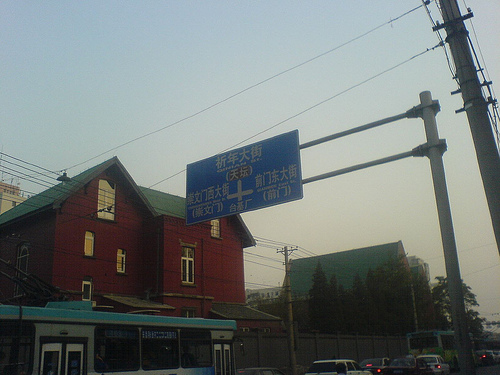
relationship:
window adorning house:
[97, 178, 117, 221] [2, 152, 284, 332]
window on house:
[97, 178, 117, 221] [5, 152, 286, 373]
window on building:
[97, 178, 117, 221] [0, 159, 254, 369]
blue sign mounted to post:
[187, 129, 303, 226] [417, 90, 476, 375]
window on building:
[181, 242, 197, 282] [0, 156, 283, 333]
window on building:
[115, 246, 129, 275] [0, 156, 283, 333]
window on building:
[97, 178, 117, 221] [0, 156, 283, 333]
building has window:
[0, 156, 283, 333] [173, 245, 198, 288]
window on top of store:
[205, 215, 224, 238] [111, 301, 242, 370]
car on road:
[305, 358, 377, 375] [212, 357, 495, 369]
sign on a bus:
[144, 327, 182, 345] [2, 296, 238, 368]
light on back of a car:
[368, 365, 377, 372] [348, 358, 426, 372]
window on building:
[97, 178, 117, 221] [6, 158, 266, 314]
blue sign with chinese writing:
[185, 130, 327, 230] [204, 155, 305, 205]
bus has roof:
[0, 300, 243, 370] [0, 303, 241, 323]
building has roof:
[0, 156, 283, 333] [0, 156, 260, 245]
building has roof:
[272, 235, 422, 373] [283, 238, 416, 303]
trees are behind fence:
[283, 246, 496, 373] [240, 324, 409, 373]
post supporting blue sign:
[299, 88, 473, 371] [187, 129, 303, 226]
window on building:
[89, 170, 121, 227] [3, 147, 248, 373]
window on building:
[97, 178, 117, 221] [3, 147, 248, 373]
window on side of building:
[97, 178, 117, 221] [3, 147, 248, 373]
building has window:
[6, 158, 283, 366] [204, 342, 236, 373]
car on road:
[412, 349, 447, 373] [283, 347, 493, 369]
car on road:
[305, 358, 377, 375] [315, 349, 496, 371]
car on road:
[305, 358, 377, 375] [261, 338, 496, 370]